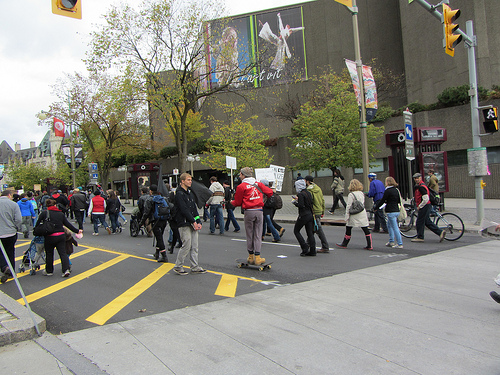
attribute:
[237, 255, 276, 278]
skateboard — black